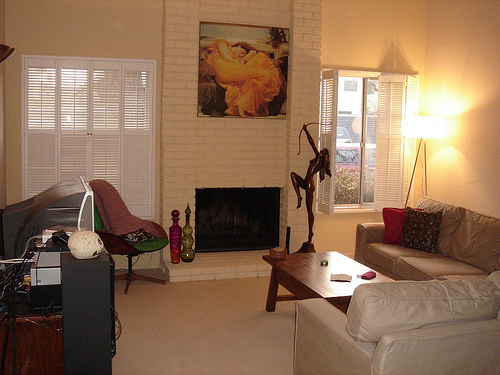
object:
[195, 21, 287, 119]
painting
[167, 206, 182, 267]
bottle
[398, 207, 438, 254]
pillow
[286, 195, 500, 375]
couch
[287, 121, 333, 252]
statue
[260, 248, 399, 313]
table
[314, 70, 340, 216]
shutter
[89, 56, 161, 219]
shutters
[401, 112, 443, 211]
lamp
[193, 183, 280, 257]
fireplace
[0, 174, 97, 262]
tv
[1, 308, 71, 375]
shelf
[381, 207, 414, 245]
pillow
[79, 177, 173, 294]
chair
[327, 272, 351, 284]
paper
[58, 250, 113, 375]
speaker